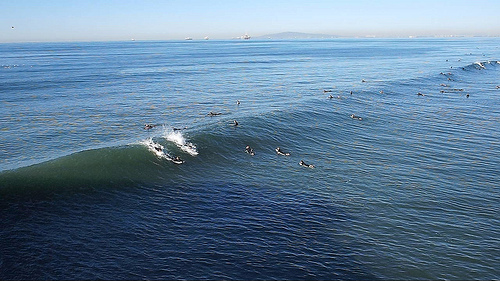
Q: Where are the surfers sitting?
A: Water.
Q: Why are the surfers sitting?
A: Waiting.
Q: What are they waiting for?
A: Waves.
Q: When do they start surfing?
A: On waves.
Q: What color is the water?
A: Blue.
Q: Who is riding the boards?
A: Surfers.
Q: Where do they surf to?
A: Beach.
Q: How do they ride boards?
A: Standing.